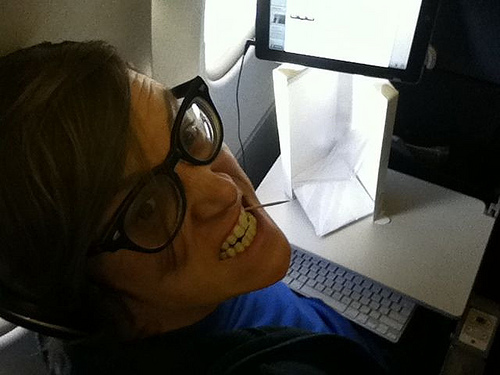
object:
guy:
[0, 26, 329, 374]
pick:
[222, 181, 302, 233]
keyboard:
[277, 245, 436, 341]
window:
[216, 11, 249, 51]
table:
[368, 209, 397, 232]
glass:
[187, 113, 210, 151]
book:
[269, 63, 397, 234]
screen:
[248, 16, 424, 91]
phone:
[4, 275, 72, 345]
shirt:
[217, 263, 383, 334]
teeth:
[226, 198, 266, 264]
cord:
[229, 26, 245, 150]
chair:
[0, 303, 133, 375]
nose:
[190, 172, 240, 221]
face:
[93, 66, 298, 305]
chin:
[267, 215, 298, 292]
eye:
[131, 179, 166, 228]